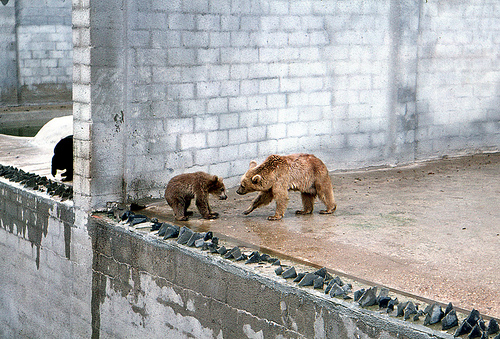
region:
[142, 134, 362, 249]
two bears are playing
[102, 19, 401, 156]
a gray stone wall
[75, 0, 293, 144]
a gray stone wall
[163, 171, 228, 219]
Small brown bear in front of big brown bear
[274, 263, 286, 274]
Gray rock sitting on the edge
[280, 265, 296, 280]
Gray rock sitting on the edge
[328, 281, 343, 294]
Gray rock sitting on the edge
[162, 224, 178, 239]
Gray rock sitting on the edge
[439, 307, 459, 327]
Gray rock sitting on the edge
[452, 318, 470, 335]
Gray rock sitting on the edge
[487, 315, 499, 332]
Gray rock sitting on the edge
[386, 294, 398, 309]
Gray rock sitting on the edge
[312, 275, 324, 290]
Gray rock sitting on the edge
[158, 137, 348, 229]
two bears in a pen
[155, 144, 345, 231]
a big bear and a small bear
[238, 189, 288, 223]
front legs of bear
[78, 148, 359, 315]
water in front a pen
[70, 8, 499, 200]
wall of pen is made of bricks of cement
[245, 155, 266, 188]
two round ears of bear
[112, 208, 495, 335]
small stones in front a pen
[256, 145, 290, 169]
a hump on back the bear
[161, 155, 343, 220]
two brown bears standing by the brick wall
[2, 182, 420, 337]
the wall at the end of the pens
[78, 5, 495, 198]
the wall separating the two pens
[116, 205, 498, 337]
assorted rocks along the end of the pen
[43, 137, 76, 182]
a darker animal in the next pen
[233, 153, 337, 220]
the bigger of the brown bears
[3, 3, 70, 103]
another brick wall at the end of the pen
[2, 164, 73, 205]
more stones at the end of the pen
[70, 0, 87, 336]
the end of the brick wall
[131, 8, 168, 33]
The cement block is gray.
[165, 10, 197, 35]
The cement block is gray.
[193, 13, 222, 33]
The cement block is gray.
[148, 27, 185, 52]
The cement block is gray.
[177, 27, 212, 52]
The cement block is gray.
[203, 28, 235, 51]
The cement block is gray.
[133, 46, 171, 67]
The cement block is gray.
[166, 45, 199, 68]
The cement block is gray.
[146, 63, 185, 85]
The cement block is gray.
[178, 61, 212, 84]
The cement block is gray.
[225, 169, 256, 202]
the face of a bear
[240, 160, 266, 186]
the ears of a bear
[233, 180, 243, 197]
the nose of a bear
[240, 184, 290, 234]
the front legs of a bear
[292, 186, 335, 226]
the back legs of a bear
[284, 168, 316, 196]
the belly of a bear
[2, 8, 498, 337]
Outside, daytime, season, unsure.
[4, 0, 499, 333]
Barren, man-made habitats with animals.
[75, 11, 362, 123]
Thick, weathered, stone wall, between enclosures.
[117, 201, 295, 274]
Ledge with sharp rocks.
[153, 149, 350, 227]
Two facing bears.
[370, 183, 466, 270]
Brown, bare surface of enclosure.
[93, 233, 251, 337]
Water stains on facade.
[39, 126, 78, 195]
Nondescript black animal.